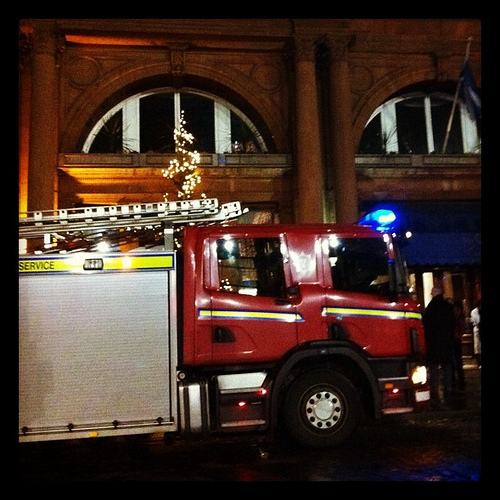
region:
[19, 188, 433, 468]
red fire truck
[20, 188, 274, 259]
ladder on top of fire truck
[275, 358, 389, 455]
front wheel on fire truck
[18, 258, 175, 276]
yellow strip on side of fire truck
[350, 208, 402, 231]
blue light on top of red fire truck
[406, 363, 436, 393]
headlight on front of red fire truck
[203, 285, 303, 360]
door on side of fire truck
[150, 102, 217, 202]
string lights on christmas tree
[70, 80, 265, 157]
arched window shape on bridge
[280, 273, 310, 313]
red rear view mirror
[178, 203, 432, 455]
the cab of a fire truck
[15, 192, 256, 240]
ladders on the top of a fire truck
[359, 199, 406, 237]
blue lights on the top of the cab of a fire truck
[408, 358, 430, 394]
the headlight of a fire truck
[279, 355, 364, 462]
a wheel of a fire truck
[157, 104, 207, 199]
the lighted top of a Christmas tree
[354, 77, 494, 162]
the windows of a building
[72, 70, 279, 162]
the windows of a building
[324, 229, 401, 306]
a window of the door of a fire truck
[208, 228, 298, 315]
a window of the door of a fire truck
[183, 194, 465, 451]
a big red truck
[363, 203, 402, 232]
blue light on truck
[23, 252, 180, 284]
yellow line on truck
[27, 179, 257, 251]
a ladder on top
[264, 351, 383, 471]
a black wheel of truck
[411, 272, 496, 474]
a man in front of truck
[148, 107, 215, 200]
top of a lit tree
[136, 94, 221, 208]
little white lights on a tree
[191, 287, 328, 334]
yellow line on red door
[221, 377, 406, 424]
red lights at bottom of truck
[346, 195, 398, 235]
a blue fire truck siren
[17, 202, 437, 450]
a red fire truck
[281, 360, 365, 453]
a black rubber fire truck tire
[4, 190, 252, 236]
a silver fire truck ladder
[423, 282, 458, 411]
a bald man in a black trench coat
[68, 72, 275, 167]
an arched building window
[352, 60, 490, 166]
an arched building window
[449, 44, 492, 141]
a flag hanging on a pole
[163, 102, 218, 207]
a tree with lights on it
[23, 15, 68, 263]
a stone building column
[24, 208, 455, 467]
This is a fire truck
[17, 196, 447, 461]
The firetruck is red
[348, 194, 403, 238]
Blue light on top of truck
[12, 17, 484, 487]
It is night time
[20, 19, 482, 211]
Building next to fire truck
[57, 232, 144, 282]
Light reflection on truck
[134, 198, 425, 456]
The truck is red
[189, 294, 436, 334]
Yellow stripe on fire truck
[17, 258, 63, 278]
The word service written on truck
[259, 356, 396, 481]
Large black tire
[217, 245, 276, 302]
window on the truck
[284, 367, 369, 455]
A tire on a truck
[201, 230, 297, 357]
A door on a truck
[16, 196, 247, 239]
Ladders on top of a truck